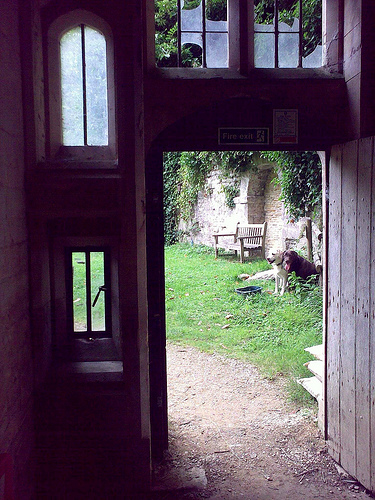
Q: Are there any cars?
A: No, there are no cars.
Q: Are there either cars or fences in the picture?
A: No, there are no cars or fences.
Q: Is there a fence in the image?
A: No, there are no fences.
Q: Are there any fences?
A: No, there are no fences.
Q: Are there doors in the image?
A: Yes, there is a door.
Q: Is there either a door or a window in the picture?
A: Yes, there is a door.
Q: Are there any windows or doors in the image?
A: Yes, there is a door.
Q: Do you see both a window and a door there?
A: Yes, there are both a door and a window.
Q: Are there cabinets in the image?
A: No, there are no cabinets.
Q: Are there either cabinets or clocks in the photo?
A: No, there are no cabinets or clocks.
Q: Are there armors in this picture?
A: No, there are no armors.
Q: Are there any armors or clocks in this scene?
A: No, there are no armors or clocks.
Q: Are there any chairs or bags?
A: Yes, there is a bag.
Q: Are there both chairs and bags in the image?
A: No, there is a bag but no chairs.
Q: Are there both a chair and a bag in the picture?
A: No, there is a bag but no chairs.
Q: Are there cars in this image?
A: No, there are no cars.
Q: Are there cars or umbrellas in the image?
A: No, there are no cars or umbrellas.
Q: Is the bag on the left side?
A: No, the bag is on the right of the image.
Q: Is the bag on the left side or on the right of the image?
A: The bag is on the right of the image.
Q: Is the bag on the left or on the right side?
A: The bag is on the right of the image.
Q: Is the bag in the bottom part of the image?
A: Yes, the bag is in the bottom of the image.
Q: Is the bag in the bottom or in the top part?
A: The bag is in the bottom of the image.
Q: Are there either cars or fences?
A: No, there are no cars or fences.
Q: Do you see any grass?
A: Yes, there is grass.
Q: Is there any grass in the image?
A: Yes, there is grass.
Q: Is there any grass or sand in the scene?
A: Yes, there is grass.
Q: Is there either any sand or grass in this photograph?
A: Yes, there is grass.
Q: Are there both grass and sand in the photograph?
A: No, there is grass but no sand.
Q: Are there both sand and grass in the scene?
A: No, there is grass but no sand.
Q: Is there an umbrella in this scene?
A: No, there are no umbrellas.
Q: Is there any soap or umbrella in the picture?
A: No, there are no umbrellas or soaps.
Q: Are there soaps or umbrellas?
A: No, there are no umbrellas or soaps.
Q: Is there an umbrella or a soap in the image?
A: No, there are no umbrellas or soaps.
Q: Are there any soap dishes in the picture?
A: No, there are no soap dishes.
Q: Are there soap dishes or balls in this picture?
A: No, there are no soap dishes or balls.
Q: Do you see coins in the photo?
A: No, there are no coins.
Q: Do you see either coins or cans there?
A: No, there are no coins or cans.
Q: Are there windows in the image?
A: Yes, there is a window.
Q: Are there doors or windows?
A: Yes, there is a window.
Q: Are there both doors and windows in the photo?
A: Yes, there are both a window and a door.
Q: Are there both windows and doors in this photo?
A: Yes, there are both a window and a door.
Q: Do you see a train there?
A: No, there are no trains.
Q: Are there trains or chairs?
A: No, there are no trains or chairs.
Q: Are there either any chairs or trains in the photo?
A: No, there are no trains or chairs.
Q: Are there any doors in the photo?
A: Yes, there is a door.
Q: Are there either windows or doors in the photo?
A: Yes, there is a door.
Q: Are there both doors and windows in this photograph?
A: Yes, there are both a door and a window.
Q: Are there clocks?
A: No, there are no clocks.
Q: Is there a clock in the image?
A: No, there are no clocks.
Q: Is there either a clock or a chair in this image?
A: No, there are no clocks or chairs.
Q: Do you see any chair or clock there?
A: No, there are no clocks or chairs.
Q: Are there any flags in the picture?
A: No, there are no flags.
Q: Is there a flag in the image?
A: No, there are no flags.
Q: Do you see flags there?
A: No, there are no flags.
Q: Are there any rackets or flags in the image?
A: No, there are no flags or rackets.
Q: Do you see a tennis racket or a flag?
A: No, there are no flags or rackets.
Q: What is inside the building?
A: The dirt is inside the building.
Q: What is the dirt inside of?
A: The dirt is inside the building.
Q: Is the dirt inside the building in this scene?
A: Yes, the dirt is inside the building.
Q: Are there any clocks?
A: No, there are no clocks.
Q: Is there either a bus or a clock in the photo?
A: No, there are no clocks or buses.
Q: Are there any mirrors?
A: No, there are no mirrors.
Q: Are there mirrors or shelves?
A: No, there are no mirrors or shelves.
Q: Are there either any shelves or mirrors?
A: No, there are no mirrors or shelves.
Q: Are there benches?
A: Yes, there is a bench.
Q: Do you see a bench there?
A: Yes, there is a bench.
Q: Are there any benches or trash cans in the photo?
A: Yes, there is a bench.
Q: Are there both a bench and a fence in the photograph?
A: No, there is a bench but no fences.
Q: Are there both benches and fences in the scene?
A: No, there is a bench but no fences.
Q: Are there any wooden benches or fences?
A: Yes, there is a wood bench.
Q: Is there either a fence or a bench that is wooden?
A: Yes, the bench is wooden.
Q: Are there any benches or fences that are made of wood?
A: Yes, the bench is made of wood.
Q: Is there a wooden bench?
A: Yes, there is a wood bench.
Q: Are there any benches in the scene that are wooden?
A: Yes, there is a bench that is wooden.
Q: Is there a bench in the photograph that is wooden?
A: Yes, there is a bench that is wooden.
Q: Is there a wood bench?
A: Yes, there is a bench that is made of wood.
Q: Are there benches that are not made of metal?
A: Yes, there is a bench that is made of wood.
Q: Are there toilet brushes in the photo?
A: No, there are no toilet brushes.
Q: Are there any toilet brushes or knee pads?
A: No, there are no toilet brushes or knee pads.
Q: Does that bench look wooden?
A: Yes, the bench is wooden.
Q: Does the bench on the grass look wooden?
A: Yes, the bench is wooden.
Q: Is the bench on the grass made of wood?
A: Yes, the bench is made of wood.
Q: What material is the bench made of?
A: The bench is made of wood.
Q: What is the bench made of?
A: The bench is made of wood.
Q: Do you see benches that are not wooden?
A: No, there is a bench but it is wooden.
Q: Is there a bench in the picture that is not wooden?
A: No, there is a bench but it is wooden.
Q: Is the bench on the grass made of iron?
A: No, the bench is made of wood.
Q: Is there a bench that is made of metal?
A: No, there is a bench but it is made of wood.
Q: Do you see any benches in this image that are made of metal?
A: No, there is a bench but it is made of wood.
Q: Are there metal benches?
A: No, there is a bench but it is made of wood.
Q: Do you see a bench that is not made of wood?
A: No, there is a bench but it is made of wood.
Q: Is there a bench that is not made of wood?
A: No, there is a bench but it is made of wood.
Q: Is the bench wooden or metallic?
A: The bench is wooden.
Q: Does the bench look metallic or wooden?
A: The bench is wooden.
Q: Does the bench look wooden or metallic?
A: The bench is wooden.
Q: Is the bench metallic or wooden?
A: The bench is wooden.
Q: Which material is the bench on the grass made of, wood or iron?
A: The bench is made of wood.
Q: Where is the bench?
A: The bench is on the grass.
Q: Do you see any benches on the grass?
A: Yes, there is a bench on the grass.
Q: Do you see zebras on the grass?
A: No, there is a bench on the grass.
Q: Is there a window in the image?
A: Yes, there is a window.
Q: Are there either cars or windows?
A: Yes, there is a window.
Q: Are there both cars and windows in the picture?
A: No, there is a window but no cars.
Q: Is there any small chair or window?
A: Yes, there is a small window.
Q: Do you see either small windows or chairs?
A: Yes, there is a small window.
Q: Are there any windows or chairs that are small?
A: Yes, the window is small.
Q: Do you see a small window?
A: Yes, there is a small window.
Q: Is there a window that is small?
A: Yes, there is a window that is small.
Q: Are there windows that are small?
A: Yes, there is a window that is small.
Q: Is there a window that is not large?
A: Yes, there is a small window.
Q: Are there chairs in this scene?
A: No, there are no chairs.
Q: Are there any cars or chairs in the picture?
A: No, there are no chairs or cars.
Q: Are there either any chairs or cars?
A: No, there are no chairs or cars.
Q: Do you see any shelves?
A: No, there are no shelves.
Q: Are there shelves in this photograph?
A: No, there are no shelves.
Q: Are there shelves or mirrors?
A: No, there are no shelves or mirrors.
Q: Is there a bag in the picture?
A: Yes, there is a bag.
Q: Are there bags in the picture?
A: Yes, there is a bag.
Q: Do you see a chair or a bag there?
A: Yes, there is a bag.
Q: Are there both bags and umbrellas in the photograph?
A: No, there is a bag but no umbrellas.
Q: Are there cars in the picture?
A: No, there are no cars.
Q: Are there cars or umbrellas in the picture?
A: No, there are no cars or umbrellas.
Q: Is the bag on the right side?
A: Yes, the bag is on the right of the image.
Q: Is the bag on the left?
A: No, the bag is on the right of the image.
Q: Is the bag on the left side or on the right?
A: The bag is on the right of the image.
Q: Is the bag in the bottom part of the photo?
A: Yes, the bag is in the bottom of the image.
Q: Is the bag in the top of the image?
A: No, the bag is in the bottom of the image.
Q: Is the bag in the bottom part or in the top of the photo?
A: The bag is in the bottom of the image.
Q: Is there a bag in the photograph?
A: Yes, there is a bag.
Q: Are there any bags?
A: Yes, there is a bag.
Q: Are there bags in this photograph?
A: Yes, there is a bag.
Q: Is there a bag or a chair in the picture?
A: Yes, there is a bag.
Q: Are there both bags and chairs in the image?
A: No, there is a bag but no chairs.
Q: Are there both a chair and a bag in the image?
A: No, there is a bag but no chairs.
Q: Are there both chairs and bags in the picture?
A: No, there is a bag but no chairs.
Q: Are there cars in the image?
A: No, there are no cars.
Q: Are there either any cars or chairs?
A: No, there are no cars or chairs.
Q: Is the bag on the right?
A: Yes, the bag is on the right of the image.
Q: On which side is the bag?
A: The bag is on the right of the image.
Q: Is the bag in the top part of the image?
A: No, the bag is in the bottom of the image.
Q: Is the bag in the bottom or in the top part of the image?
A: The bag is in the bottom of the image.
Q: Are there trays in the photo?
A: No, there are no trays.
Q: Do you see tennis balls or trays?
A: No, there are no trays or tennis balls.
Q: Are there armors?
A: No, there are no armors.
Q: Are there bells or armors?
A: No, there are no armors or bells.